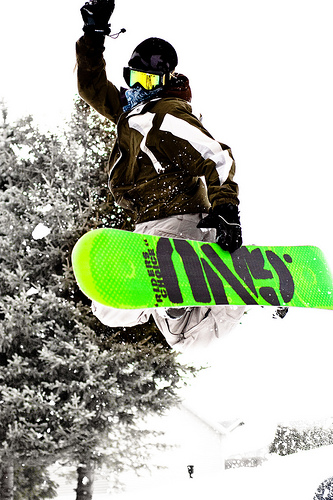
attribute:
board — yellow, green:
[67, 218, 331, 326]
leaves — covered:
[2, 83, 193, 498]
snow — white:
[107, 440, 332, 499]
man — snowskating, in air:
[54, 5, 292, 347]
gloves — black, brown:
[75, 2, 245, 255]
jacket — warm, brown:
[78, 31, 243, 215]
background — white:
[4, 4, 330, 498]